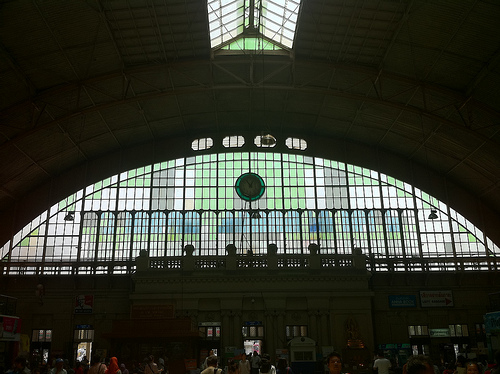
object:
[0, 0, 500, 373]
building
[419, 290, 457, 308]
advertisement sign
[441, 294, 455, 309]
arrow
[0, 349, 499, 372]
crowd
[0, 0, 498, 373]
station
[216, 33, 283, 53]
window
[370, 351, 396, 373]
man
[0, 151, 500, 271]
glass doorway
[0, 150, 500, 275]
half circle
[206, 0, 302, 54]
skylight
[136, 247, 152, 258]
speaker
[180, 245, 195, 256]
speaker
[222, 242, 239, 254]
speaker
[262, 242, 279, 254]
speaker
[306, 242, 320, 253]
speaker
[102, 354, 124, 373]
woman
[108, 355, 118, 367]
head covering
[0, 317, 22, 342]
sign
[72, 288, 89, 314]
advertisement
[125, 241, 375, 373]
restaraunt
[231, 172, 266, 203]
clock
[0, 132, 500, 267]
wall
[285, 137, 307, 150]
window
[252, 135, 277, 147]
window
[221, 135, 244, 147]
window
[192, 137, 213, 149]
window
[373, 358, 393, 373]
shirt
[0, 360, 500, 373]
line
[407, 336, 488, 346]
counters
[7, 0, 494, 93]
roof